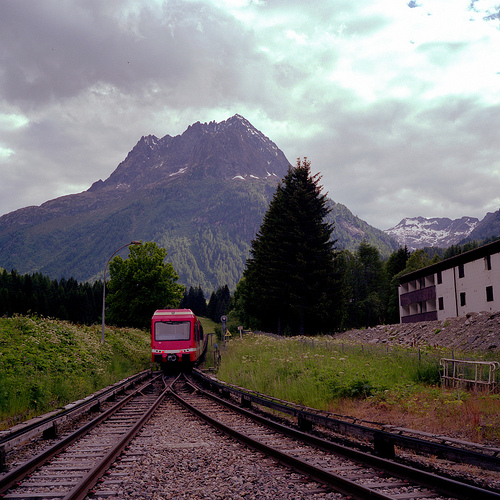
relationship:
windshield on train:
[157, 317, 193, 341] [149, 307, 203, 376]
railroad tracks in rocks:
[3, 366, 499, 498] [0, 371, 447, 499]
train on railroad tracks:
[149, 307, 203, 376] [0, 366, 499, 499]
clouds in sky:
[0, 0, 245, 207] [2, 1, 498, 229]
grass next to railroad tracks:
[0, 308, 152, 426] [3, 366, 499, 498]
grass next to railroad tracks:
[213, 325, 499, 409] [3, 366, 499, 498]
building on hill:
[393, 239, 499, 320] [335, 309, 499, 351]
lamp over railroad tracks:
[98, 238, 142, 331] [3, 366, 499, 498]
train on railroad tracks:
[150, 308, 214, 370] [0, 366, 499, 499]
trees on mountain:
[1, 179, 399, 296] [0, 113, 499, 303]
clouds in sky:
[238, 0, 500, 232] [238, 24, 456, 131]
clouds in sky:
[238, 0, 500, 232] [268, 11, 497, 114]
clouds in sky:
[238, 0, 500, 232] [252, 0, 488, 193]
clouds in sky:
[64, 33, 180, 103] [185, 41, 494, 207]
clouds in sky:
[0, 0, 245, 207] [12, 35, 494, 223]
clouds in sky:
[238, 0, 500, 232] [313, 16, 493, 171]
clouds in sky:
[238, 0, 500, 232] [313, 30, 496, 167]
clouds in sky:
[238, 0, 500, 232] [336, 32, 491, 128]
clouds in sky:
[238, 0, 500, 232] [253, 33, 326, 83]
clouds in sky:
[0, 0, 245, 207] [69, 6, 474, 142]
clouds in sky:
[0, 0, 245, 207] [284, 22, 404, 133]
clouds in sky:
[365, 96, 411, 147] [286, 30, 466, 196]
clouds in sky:
[238, 0, 500, 232] [290, 6, 494, 166]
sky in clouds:
[319, 24, 490, 207] [388, 131, 497, 207]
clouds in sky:
[238, 0, 500, 232] [254, 30, 455, 158]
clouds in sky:
[0, 0, 245, 207] [102, 16, 436, 141]